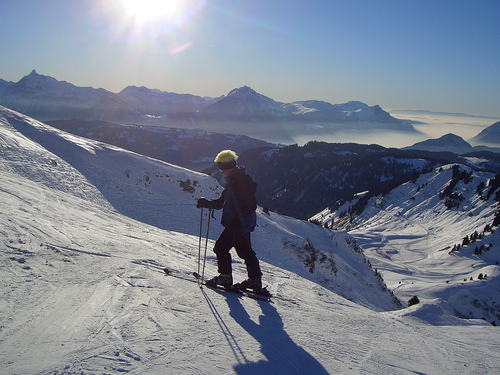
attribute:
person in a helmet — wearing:
[210, 146, 248, 173]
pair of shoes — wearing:
[200, 256, 279, 293]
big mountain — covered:
[14, 58, 118, 121]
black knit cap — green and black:
[202, 235, 230, 270]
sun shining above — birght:
[82, 3, 219, 54]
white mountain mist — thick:
[117, 71, 314, 155]